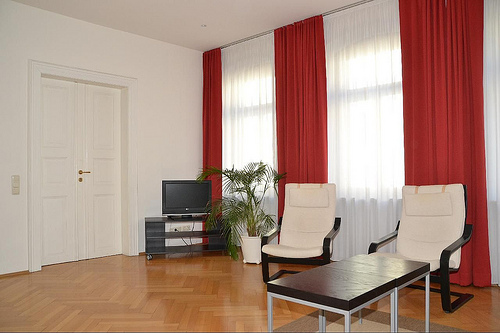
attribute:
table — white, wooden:
[265, 250, 429, 331]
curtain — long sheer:
[212, 40, 279, 262]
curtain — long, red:
[198, 46, 230, 208]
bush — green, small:
[196, 162, 284, 260]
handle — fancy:
[73, 167, 94, 179]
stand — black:
[114, 202, 247, 272]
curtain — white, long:
[324, 9, 406, 259]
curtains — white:
[221, 29, 278, 209]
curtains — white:
[321, 2, 405, 270]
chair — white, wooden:
[260, 181, 341, 284]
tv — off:
[158, 177, 213, 217]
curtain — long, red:
[400, 1, 487, 286]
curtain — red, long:
[397, 2, 496, 295]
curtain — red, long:
[261, 22, 366, 269]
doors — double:
[33, 62, 155, 274]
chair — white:
[381, 180, 468, 274]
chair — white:
[261, 174, 341, 262]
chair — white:
[229, 175, 339, 300]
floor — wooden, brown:
[0, 243, 500, 331]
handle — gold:
[47, 149, 107, 221]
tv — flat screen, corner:
[153, 176, 213, 207]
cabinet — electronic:
[144, 215, 233, 260]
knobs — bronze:
[61, 147, 127, 188]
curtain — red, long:
[276, 31, 357, 206]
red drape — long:
[203, 57, 221, 160]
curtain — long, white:
[220, 30, 276, 246]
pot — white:
[232, 225, 274, 273]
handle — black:
[418, 234, 474, 322]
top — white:
[285, 180, 325, 239]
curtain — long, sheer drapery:
[203, 38, 414, 181]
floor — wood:
[77, 281, 217, 330]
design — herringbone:
[41, 267, 223, 327]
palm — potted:
[207, 153, 272, 227]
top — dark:
[293, 272, 376, 295]